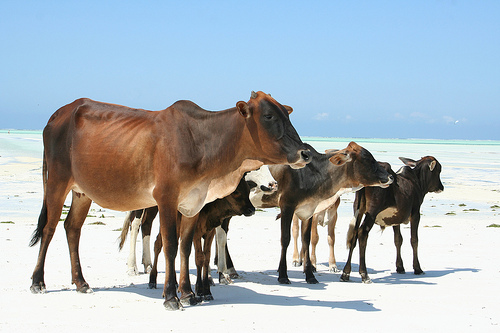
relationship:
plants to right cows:
[447, 195, 495, 232] [338, 155, 444, 283]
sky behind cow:
[0, 0, 500, 138] [27, 90, 313, 311]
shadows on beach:
[145, 270, 290, 310] [49, 243, 159, 286]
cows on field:
[48, 86, 408, 295] [377, 241, 472, 290]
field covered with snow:
[377, 241, 472, 290] [250, 263, 326, 303]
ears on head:
[220, 86, 319, 181] [229, 93, 292, 111]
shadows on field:
[215, 282, 317, 312] [0, 143, 500, 333]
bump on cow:
[161, 93, 191, 123] [45, 96, 307, 286]